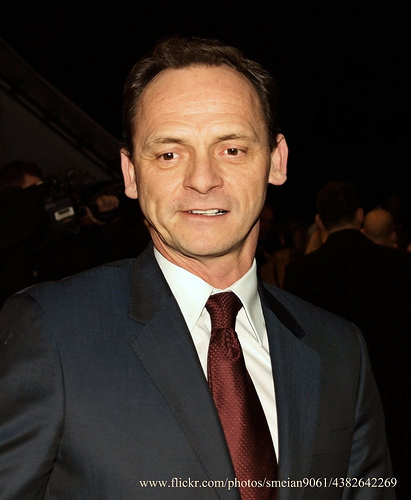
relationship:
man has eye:
[2, 36, 397, 500] [154, 147, 182, 162]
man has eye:
[2, 36, 397, 500] [220, 146, 250, 159]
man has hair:
[2, 36, 397, 500] [119, 34, 279, 151]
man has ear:
[2, 36, 397, 500] [119, 146, 141, 204]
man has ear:
[2, 36, 397, 500] [269, 130, 291, 188]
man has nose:
[2, 36, 397, 500] [184, 153, 226, 194]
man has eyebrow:
[2, 36, 397, 500] [214, 129, 255, 148]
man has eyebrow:
[2, 36, 397, 500] [136, 135, 185, 153]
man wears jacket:
[2, 36, 397, 500] [0, 242, 397, 497]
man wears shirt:
[2, 36, 397, 500] [147, 247, 289, 470]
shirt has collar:
[147, 247, 289, 470] [149, 248, 278, 350]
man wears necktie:
[2, 36, 397, 500] [203, 293, 284, 500]